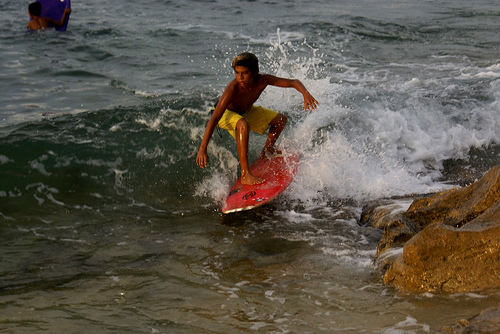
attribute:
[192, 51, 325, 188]
boy — surfing, bending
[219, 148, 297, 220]
surfboard — red, blue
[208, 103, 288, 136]
shorts — yellow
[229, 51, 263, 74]
hair — blonde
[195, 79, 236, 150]
arm — extended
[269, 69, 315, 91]
arm — bent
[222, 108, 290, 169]
legs — bent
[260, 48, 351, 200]
water — splashing